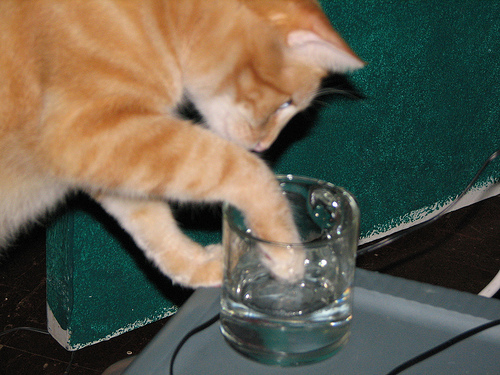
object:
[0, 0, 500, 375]
scene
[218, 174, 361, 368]
glass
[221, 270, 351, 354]
water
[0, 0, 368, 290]
cat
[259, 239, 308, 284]
paw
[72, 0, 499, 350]
wall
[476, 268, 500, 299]
power cord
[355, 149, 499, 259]
black power cord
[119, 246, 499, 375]
storage lid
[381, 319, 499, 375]
black power cord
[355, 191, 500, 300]
floor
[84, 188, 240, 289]
front legs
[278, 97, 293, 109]
eye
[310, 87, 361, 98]
whiskers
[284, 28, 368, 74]
ear